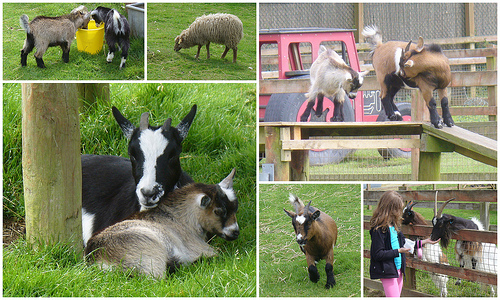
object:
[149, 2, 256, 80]
grass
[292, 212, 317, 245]
goat head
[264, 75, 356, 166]
tires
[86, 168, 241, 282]
brown/white goat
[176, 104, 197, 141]
ear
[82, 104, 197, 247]
animal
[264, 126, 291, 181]
post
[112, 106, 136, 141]
black ear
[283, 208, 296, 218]
black ear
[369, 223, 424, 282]
black coat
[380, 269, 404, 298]
pants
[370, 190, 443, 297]
girl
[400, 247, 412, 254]
hand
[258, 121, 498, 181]
railing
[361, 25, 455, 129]
goat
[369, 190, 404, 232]
hair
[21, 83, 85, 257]
pole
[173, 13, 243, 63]
goats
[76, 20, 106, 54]
water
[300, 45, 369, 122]
goat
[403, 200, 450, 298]
goat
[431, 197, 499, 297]
goat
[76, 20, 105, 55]
bucket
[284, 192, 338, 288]
goat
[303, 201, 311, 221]
horns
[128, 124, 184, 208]
head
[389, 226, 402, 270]
shirt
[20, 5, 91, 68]
dog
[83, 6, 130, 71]
dog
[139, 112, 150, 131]
horn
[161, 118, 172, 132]
horn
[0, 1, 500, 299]
photo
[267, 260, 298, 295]
grass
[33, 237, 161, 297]
grass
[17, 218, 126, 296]
ground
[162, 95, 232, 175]
right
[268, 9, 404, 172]
background